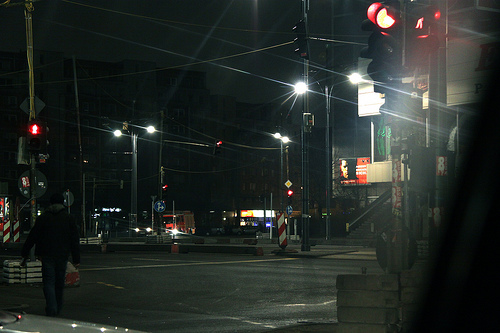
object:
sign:
[154, 201, 166, 212]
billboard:
[339, 157, 371, 185]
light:
[359, 0, 440, 84]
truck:
[163, 213, 211, 235]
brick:
[336, 274, 427, 333]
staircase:
[346, 188, 392, 239]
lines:
[80, 258, 299, 271]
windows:
[370, 115, 392, 162]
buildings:
[0, 51, 209, 236]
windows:
[250, 183, 257, 191]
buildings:
[357, 0, 498, 246]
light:
[349, 73, 361, 84]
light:
[282, 136, 290, 143]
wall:
[335, 138, 351, 153]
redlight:
[376, 7, 396, 28]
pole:
[325, 85, 332, 240]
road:
[0, 235, 385, 333]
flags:
[276, 212, 288, 247]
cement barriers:
[2, 259, 42, 284]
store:
[235, 210, 275, 232]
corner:
[181, 236, 273, 254]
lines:
[82, 110, 280, 168]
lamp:
[273, 132, 281, 138]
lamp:
[147, 126, 156, 134]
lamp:
[114, 130, 122, 137]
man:
[20, 192, 81, 316]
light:
[294, 81, 308, 94]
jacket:
[21, 212, 81, 265]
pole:
[301, 59, 309, 251]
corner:
[0, 257, 119, 333]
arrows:
[157, 203, 164, 211]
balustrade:
[346, 188, 393, 239]